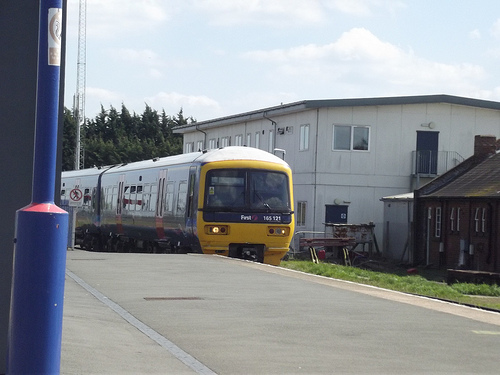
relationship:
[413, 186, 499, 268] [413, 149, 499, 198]
house with roof